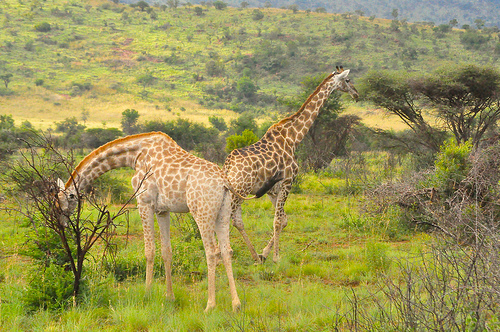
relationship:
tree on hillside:
[120, 105, 139, 133] [0, 1, 499, 148]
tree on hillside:
[135, 69, 154, 91] [1, 72, 471, 166]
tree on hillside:
[34, 78, 43, 86] [0, 1, 499, 148]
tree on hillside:
[161, 48, 197, 76] [5, 7, 463, 151]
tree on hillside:
[193, 55, 230, 87] [9, 4, 479, 162]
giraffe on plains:
[53, 130, 284, 314] [5, 176, 482, 321]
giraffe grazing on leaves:
[53, 130, 284, 314] [26, 210, 98, 316]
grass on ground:
[5, 134, 498, 323] [11, 185, 481, 323]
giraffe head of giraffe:
[329, 56, 366, 117] [172, 48, 360, 281]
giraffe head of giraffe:
[46, 169, 84, 239] [53, 130, 284, 314]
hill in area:
[2, 2, 498, 112] [0, 174, 500, 332]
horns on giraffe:
[333, 62, 345, 72] [172, 48, 360, 281]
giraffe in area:
[222, 64, 359, 262] [5, 157, 485, 320]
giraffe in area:
[48, 123, 243, 318] [5, 157, 485, 320]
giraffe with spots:
[222, 64, 359, 262] [239, 100, 318, 181]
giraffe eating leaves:
[53, 130, 284, 314] [19, 202, 75, 307]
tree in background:
[0, 73, 15, 89] [9, 1, 478, 138]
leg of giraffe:
[187, 201, 218, 312] [53, 130, 284, 314]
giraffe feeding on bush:
[53, 130, 284, 314] [0, 129, 152, 303]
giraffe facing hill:
[222, 64, 359, 262] [2, 2, 246, 112]